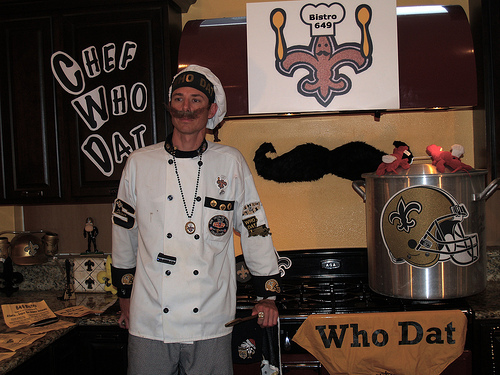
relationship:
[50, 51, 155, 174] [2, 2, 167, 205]
writing on cupboard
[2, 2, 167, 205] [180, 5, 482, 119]
cupboard by oven hood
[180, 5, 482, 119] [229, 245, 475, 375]
oven hood by stove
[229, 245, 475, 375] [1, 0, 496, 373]
stove in kitchen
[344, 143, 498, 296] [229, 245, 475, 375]
pot on stove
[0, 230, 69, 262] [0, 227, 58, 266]
beer cans are on hat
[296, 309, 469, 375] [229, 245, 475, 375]
towel hanging on stove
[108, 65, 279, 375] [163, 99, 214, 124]
man wearing a fake mustache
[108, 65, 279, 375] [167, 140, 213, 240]
man wearing a necklace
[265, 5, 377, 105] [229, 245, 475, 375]
image over stove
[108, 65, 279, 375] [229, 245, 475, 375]
man leaning against a stove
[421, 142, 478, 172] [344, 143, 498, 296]
crawdad on pot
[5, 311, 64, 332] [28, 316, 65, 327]
knife has a handle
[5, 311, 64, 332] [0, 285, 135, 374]
knife on counter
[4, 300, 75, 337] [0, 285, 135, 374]
paper on counter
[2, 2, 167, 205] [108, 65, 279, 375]
cupboard behind man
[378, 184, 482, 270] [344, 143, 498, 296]
logo on pot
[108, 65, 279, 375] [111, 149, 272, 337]
man wearing a chef's jacket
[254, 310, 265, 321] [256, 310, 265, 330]
ring on finger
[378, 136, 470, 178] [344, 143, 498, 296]
stuffed animals are on pot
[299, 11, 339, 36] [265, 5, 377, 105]
bistro 649 on image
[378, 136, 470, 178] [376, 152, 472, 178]
stuffed animals are on lid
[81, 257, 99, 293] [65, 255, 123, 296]
spades are on decor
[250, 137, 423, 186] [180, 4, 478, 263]
mustache on wall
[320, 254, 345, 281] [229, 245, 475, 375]
control panel on stove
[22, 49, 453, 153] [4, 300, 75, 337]
advertisements are in paper